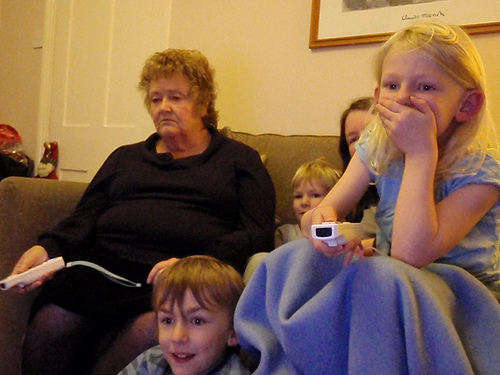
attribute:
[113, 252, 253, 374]
boy — sitting, smiling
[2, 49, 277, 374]
woman — old, frowning, playing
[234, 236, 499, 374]
blanket — purple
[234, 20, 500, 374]
girl — blonde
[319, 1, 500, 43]
picture — white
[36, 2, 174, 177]
door — white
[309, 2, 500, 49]
frame — brown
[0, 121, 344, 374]
couch — brown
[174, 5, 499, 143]
wall — beige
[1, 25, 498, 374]
family — bonding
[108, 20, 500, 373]
children — playing